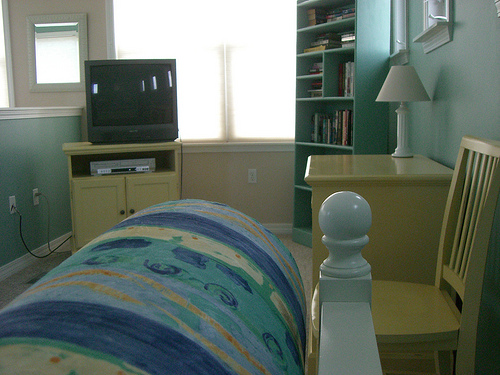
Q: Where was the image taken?
A: It was taken at the bedroom.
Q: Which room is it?
A: It is a bedroom.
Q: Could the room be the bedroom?
A: Yes, it is the bedroom.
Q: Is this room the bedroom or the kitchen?
A: It is the bedroom.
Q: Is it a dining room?
A: No, it is a bedroom.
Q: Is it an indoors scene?
A: Yes, it is indoors.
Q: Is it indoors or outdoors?
A: It is indoors.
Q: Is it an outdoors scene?
A: No, it is indoors.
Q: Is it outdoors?
A: No, it is indoors.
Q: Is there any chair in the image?
A: Yes, there is a chair.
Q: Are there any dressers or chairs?
A: Yes, there is a chair.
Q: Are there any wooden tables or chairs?
A: Yes, there is a wood chair.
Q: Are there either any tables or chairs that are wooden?
A: Yes, the chair is wooden.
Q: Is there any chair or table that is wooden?
A: Yes, the chair is wooden.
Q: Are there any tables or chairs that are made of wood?
A: Yes, the chair is made of wood.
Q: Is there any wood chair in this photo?
A: Yes, there is a chair that is made of wood.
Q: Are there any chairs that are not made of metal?
A: Yes, there is a chair that is made of wood.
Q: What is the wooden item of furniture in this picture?
A: The piece of furniture is a chair.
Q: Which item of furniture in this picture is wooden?
A: The piece of furniture is a chair.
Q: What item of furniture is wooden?
A: The piece of furniture is a chair.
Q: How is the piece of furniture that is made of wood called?
A: The piece of furniture is a chair.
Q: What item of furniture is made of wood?
A: The piece of furniture is a chair.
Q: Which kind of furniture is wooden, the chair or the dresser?
A: The chair is wooden.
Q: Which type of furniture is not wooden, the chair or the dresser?
A: The dresser is not wooden.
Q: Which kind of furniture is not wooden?
A: The furniture is a dresser.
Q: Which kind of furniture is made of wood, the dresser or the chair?
A: The chair is made of wood.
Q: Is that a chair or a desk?
A: That is a chair.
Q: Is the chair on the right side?
A: Yes, the chair is on the right of the image.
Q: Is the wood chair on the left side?
A: No, the chair is on the right of the image.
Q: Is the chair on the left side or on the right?
A: The chair is on the right of the image.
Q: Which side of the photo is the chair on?
A: The chair is on the right of the image.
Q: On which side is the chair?
A: The chair is on the right of the image.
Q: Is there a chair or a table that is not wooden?
A: No, there is a chair but it is wooden.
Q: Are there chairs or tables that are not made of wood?
A: No, there is a chair but it is made of wood.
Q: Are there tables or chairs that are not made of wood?
A: No, there is a chair but it is made of wood.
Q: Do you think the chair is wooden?
A: Yes, the chair is wooden.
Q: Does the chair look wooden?
A: Yes, the chair is wooden.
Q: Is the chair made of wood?
A: Yes, the chair is made of wood.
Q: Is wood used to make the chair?
A: Yes, the chair is made of wood.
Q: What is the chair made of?
A: The chair is made of wood.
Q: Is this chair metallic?
A: No, the chair is wooden.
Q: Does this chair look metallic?
A: No, the chair is wooden.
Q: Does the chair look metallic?
A: No, the chair is wooden.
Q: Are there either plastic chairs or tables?
A: No, there is a chair but it is wooden.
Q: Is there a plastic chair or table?
A: No, there is a chair but it is wooden.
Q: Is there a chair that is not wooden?
A: No, there is a chair but it is wooden.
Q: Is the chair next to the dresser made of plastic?
A: No, the chair is made of wood.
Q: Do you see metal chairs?
A: No, there is a chair but it is made of wood.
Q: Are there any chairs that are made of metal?
A: No, there is a chair but it is made of wood.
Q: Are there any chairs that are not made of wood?
A: No, there is a chair but it is made of wood.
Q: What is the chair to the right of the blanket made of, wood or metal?
A: The chair is made of wood.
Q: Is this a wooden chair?
A: Yes, this is a wooden chair.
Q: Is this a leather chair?
A: No, this is a wooden chair.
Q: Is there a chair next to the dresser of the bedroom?
A: Yes, there is a chair next to the dresser.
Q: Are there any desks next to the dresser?
A: No, there is a chair next to the dresser.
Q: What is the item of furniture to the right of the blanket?
A: The piece of furniture is a chair.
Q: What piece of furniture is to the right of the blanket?
A: The piece of furniture is a chair.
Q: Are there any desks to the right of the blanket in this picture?
A: No, there is a chair to the right of the blanket.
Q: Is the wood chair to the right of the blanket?
A: Yes, the chair is to the right of the blanket.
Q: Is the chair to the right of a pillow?
A: No, the chair is to the right of the blanket.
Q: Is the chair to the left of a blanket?
A: No, the chair is to the right of a blanket.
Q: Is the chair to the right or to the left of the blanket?
A: The chair is to the right of the blanket.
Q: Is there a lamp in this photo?
A: Yes, there is a lamp.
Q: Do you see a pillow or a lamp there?
A: Yes, there is a lamp.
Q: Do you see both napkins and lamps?
A: No, there is a lamp but no napkins.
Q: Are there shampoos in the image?
A: No, there are no shampoos.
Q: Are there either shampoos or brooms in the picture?
A: No, there are no shampoos or brooms.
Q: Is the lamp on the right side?
A: Yes, the lamp is on the right of the image.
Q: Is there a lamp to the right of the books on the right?
A: Yes, there is a lamp to the right of the books.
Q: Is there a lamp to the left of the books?
A: No, the lamp is to the right of the books.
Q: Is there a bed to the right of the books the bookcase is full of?
A: No, there is a lamp to the right of the books.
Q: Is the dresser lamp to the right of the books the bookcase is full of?
A: Yes, the lamp is to the right of the books.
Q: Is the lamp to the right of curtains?
A: No, the lamp is to the right of the books.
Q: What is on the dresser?
A: The lamp is on the dresser.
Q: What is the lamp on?
A: The lamp is on the dresser.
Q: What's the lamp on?
A: The lamp is on the dresser.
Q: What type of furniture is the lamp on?
A: The lamp is on the dresser.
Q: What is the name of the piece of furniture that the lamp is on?
A: The piece of furniture is a dresser.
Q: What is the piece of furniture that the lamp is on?
A: The piece of furniture is a dresser.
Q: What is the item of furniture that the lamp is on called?
A: The piece of furniture is a dresser.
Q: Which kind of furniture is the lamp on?
A: The lamp is on the dresser.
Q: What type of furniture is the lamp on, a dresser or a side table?
A: The lamp is on a dresser.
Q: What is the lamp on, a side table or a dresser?
A: The lamp is on a dresser.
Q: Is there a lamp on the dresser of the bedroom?
A: Yes, there is a lamp on the dresser.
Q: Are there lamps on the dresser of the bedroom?
A: Yes, there is a lamp on the dresser.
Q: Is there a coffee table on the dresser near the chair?
A: No, there is a lamp on the dresser.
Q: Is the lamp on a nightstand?
A: No, the lamp is on a dresser.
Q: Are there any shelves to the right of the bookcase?
A: No, there is a lamp to the right of the bookcase.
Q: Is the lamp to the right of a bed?
A: No, the lamp is to the right of a bookcase.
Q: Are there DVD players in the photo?
A: Yes, there is a DVD player.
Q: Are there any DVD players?
A: Yes, there is a DVD player.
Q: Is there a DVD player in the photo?
A: Yes, there is a DVD player.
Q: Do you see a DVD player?
A: Yes, there is a DVD player.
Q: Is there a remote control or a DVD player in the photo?
A: Yes, there is a DVD player.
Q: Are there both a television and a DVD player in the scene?
A: Yes, there are both a DVD player and a television.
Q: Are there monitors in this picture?
A: No, there are no monitors.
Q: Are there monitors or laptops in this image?
A: No, there are no monitors or laptops.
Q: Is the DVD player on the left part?
A: Yes, the DVD player is on the left of the image.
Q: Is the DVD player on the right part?
A: No, the DVD player is on the left of the image.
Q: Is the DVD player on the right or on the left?
A: The DVD player is on the left of the image.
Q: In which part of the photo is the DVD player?
A: The DVD player is on the left of the image.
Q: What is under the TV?
A: The DVD player is under the TV.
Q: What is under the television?
A: The DVD player is under the TV.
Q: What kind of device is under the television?
A: The device is a DVD player.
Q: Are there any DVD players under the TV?
A: Yes, there is a DVD player under the TV.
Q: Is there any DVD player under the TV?
A: Yes, there is a DVD player under the TV.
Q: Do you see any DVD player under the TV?
A: Yes, there is a DVD player under the TV.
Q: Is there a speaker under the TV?
A: No, there is a DVD player under the TV.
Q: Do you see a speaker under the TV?
A: No, there is a DVD player under the TV.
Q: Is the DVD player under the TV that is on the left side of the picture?
A: Yes, the DVD player is under the TV.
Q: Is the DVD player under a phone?
A: No, the DVD player is under the TV.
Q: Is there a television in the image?
A: Yes, there is a television.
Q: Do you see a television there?
A: Yes, there is a television.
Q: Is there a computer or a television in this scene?
A: Yes, there is a television.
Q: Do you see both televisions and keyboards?
A: No, there is a television but no keyboards.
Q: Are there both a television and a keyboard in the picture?
A: No, there is a television but no keyboards.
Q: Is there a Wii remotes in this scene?
A: No, there are no Wii controllers.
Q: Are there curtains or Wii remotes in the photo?
A: No, there are no Wii remotes or curtains.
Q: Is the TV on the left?
A: Yes, the TV is on the left of the image.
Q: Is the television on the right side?
A: No, the television is on the left of the image.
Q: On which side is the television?
A: The television is on the left of the image.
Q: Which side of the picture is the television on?
A: The television is on the left of the image.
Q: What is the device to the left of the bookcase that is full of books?
A: The device is a television.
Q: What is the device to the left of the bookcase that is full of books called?
A: The device is a television.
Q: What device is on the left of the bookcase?
A: The device is a television.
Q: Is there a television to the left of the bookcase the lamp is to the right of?
A: Yes, there is a television to the left of the bookcase.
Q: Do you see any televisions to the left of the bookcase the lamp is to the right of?
A: Yes, there is a television to the left of the bookcase.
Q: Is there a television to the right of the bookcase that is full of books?
A: No, the television is to the left of the bookcase.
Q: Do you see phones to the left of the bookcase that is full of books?
A: No, there is a television to the left of the bookcase.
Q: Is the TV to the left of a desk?
A: No, the TV is to the left of a bookcase.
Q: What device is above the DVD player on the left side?
A: The device is a television.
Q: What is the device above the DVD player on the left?
A: The device is a television.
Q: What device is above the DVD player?
A: The device is a television.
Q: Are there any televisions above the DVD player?
A: Yes, there is a television above the DVD player.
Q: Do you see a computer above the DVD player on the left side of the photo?
A: No, there is a television above the DVD player.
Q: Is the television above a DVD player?
A: Yes, the television is above a DVD player.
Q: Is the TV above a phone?
A: No, the TV is above a DVD player.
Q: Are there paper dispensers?
A: No, there are no paper dispensers.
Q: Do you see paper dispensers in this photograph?
A: No, there are no paper dispensers.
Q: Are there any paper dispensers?
A: No, there are no paper dispensers.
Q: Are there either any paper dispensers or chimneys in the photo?
A: No, there are no paper dispensers or chimneys.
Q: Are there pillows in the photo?
A: No, there are no pillows.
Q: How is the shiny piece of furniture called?
A: The piece of furniture is a dresser.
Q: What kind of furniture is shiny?
A: The furniture is a dresser.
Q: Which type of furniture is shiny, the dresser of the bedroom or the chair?
A: The dresser is shiny.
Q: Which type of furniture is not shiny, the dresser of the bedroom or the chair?
A: The chair is not shiny.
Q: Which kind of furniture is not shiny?
A: The furniture is a chair.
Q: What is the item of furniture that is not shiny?
A: The piece of furniture is a chair.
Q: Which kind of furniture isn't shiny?
A: The furniture is a chair.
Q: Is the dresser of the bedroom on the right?
A: Yes, the dresser is on the right of the image.